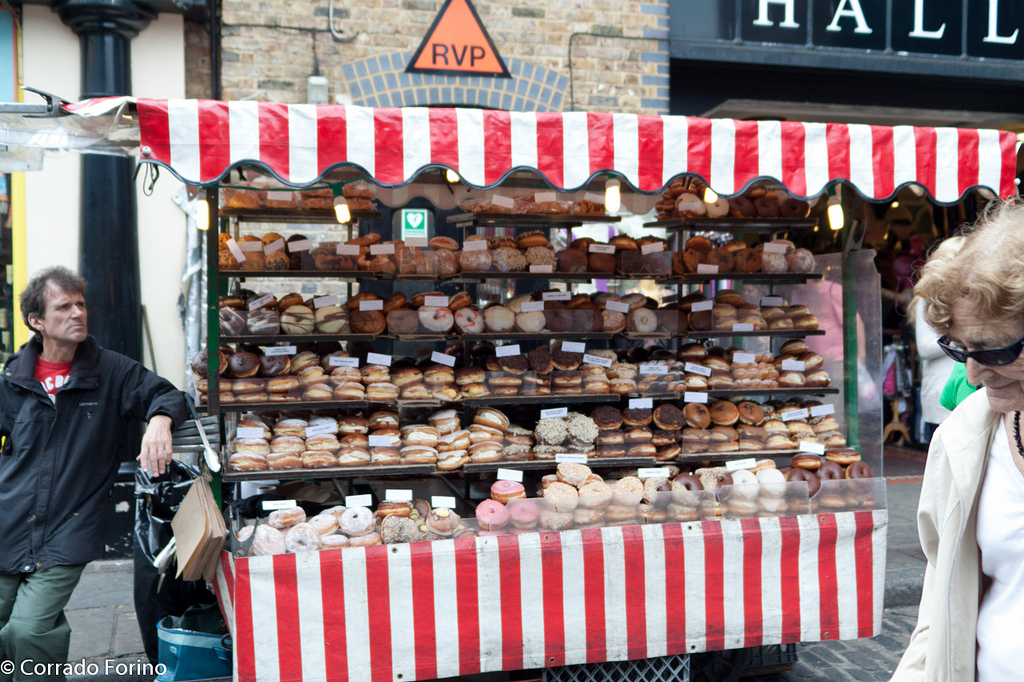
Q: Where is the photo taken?
A: Outdoors.